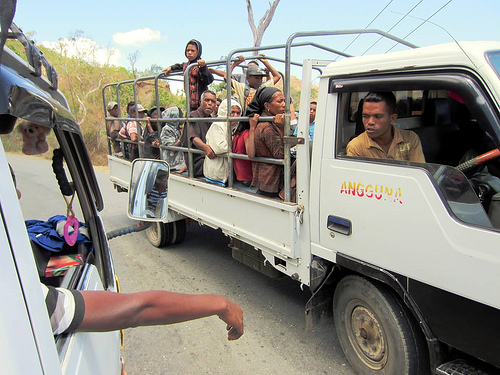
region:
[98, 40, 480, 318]
vehicle with people in it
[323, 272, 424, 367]
front tire on the vehicle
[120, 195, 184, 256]
rear tires on the vehicle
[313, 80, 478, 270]
door to the vehicle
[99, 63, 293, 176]
passengers in back of truck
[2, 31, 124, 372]
vehicle across from truck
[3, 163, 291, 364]
street with vehicles on it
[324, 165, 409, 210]
name on the truck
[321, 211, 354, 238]
handle on the door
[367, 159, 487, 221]
window on the truck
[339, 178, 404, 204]
signage on side of a truck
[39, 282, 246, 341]
person's arm hanging out of a window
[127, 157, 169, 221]
side mirror on a vehicle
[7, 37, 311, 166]
hill covered in plants on side of road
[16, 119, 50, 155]
stuffed animal hanging in car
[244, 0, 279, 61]
barren tree beside a road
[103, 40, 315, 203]
group of people in the bed of a truck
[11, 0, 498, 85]
white clouds in a blue sky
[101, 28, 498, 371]
white truck carrying several passengers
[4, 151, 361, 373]
asphalt road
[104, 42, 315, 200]
people riding in back of truck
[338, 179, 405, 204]
truck says ANGGUNA on side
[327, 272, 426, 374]
dirty tires on vehicle front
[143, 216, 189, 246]
dual tires on back of truck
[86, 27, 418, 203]
metal ribs cover truck bed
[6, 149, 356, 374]
light gray paved road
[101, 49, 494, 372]
the truck is white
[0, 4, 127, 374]
white vehicle going opposite way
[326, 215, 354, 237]
black door handle on truck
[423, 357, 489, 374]
metal plate under door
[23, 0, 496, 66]
blue of daytime sky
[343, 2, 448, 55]
three wires suspended in the air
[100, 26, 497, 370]
people in back of truck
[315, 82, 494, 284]
driver in truck window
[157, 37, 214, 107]
boy holding onto bars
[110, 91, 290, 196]
row of seated people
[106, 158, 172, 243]
mirror on side of vehicle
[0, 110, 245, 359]
arm resting on vehicle door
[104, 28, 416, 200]
metal bars on truck bed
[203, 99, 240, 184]
person in hooded jacket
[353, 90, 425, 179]
person looking out the window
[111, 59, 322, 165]
people in the back of truck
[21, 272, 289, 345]
person's arm hanging out window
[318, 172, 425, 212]
letters on side of truck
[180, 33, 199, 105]
boy standing on the truck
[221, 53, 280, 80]
arms hanging on to bar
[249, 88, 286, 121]
woman with black scarf on head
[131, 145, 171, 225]
reflection in side mirror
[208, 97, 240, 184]
woman with white hood and jacket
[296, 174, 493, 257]
truck is white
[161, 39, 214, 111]
A person standing up on truck bed with a black hoodie on.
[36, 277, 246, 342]
A person's right arm hanging out of a vehicle.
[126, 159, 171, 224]
A rear view mirror on a barely visible vehicle.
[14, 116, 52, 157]
A tan bear hanging inside a truck.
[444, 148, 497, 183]
A red and grey steering wheel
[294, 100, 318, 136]
A boy in the back of a truck in a blue shirt with black hair.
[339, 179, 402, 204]
The orange and red word ANGGUNA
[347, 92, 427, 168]
A black haired man driving a truck in a mustard colored shirt.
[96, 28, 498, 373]
A white truck with long back filled with people.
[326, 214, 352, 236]
A black truck door handle.